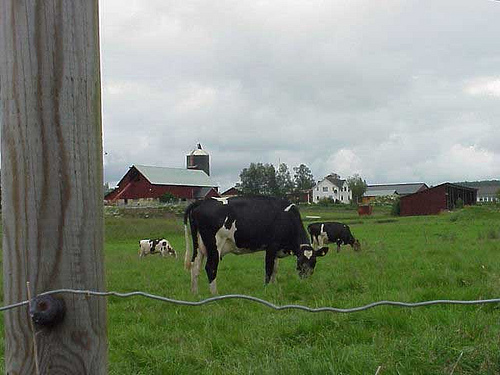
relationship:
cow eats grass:
[183, 192, 330, 298] [106, 205, 497, 373]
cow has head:
[175, 191, 327, 296] [291, 243, 326, 281]